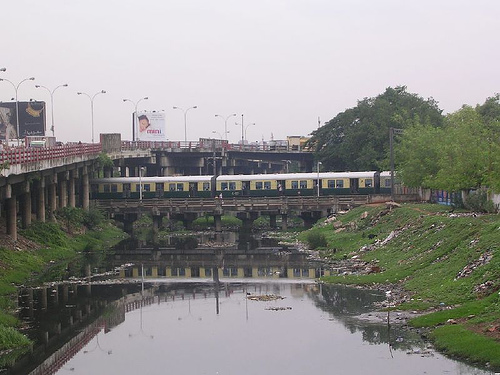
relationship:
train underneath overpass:
[73, 161, 450, 230] [3, 122, 385, 173]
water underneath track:
[0, 225, 497, 374] [108, 189, 387, 229]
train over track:
[73, 161, 450, 230] [108, 189, 387, 229]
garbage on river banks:
[325, 202, 392, 232] [299, 194, 497, 355]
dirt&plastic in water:
[247, 290, 278, 302] [0, 225, 497, 374]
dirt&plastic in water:
[41, 264, 136, 284] [0, 225, 497, 374]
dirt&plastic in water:
[198, 231, 235, 251] [0, 225, 497, 374]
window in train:
[166, 182, 183, 192] [73, 161, 450, 230]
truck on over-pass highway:
[23, 136, 58, 154] [0, 144, 162, 218]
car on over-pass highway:
[55, 140, 65, 149] [0, 144, 162, 218]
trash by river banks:
[449, 249, 496, 274] [299, 194, 497, 355]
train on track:
[73, 161, 450, 230] [108, 189, 387, 229]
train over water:
[73, 161, 450, 230] [0, 225, 497, 374]